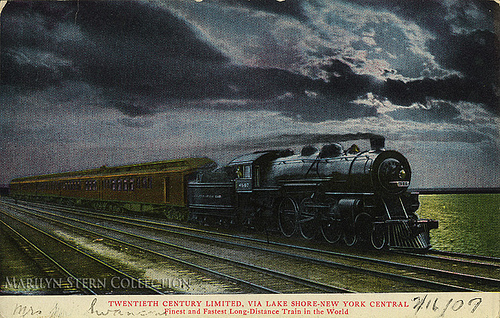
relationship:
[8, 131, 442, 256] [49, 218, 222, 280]
train moving track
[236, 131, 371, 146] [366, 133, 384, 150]
smoke from chimney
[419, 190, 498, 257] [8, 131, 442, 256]
field behind train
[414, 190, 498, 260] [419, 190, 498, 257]
grass on field